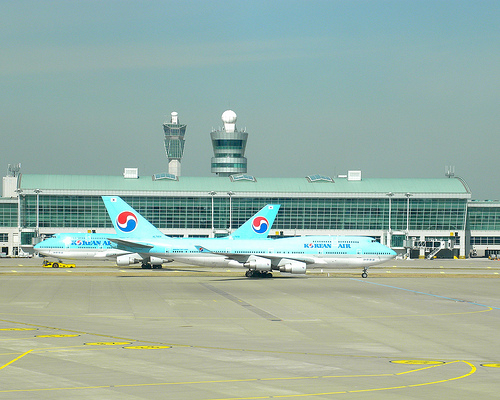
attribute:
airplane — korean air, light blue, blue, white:
[101, 195, 398, 277]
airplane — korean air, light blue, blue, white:
[34, 204, 282, 268]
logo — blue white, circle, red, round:
[116, 211, 139, 233]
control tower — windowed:
[210, 109, 248, 176]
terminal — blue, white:
[1, 162, 499, 259]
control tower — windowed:
[162, 111, 187, 177]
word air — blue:
[338, 244, 351, 249]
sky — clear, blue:
[1, 0, 499, 200]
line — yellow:
[0, 305, 492, 319]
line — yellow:
[0, 360, 460, 392]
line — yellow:
[199, 360, 475, 400]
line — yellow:
[0, 345, 89, 371]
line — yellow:
[0, 346, 122, 356]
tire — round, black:
[361, 273, 368, 279]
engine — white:
[243, 259, 271, 271]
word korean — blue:
[303, 243, 331, 248]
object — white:
[221, 110, 237, 132]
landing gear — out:
[361, 267, 367, 278]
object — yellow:
[44, 262, 76, 269]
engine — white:
[279, 262, 306, 273]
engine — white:
[116, 256, 138, 266]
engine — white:
[150, 256, 171, 265]